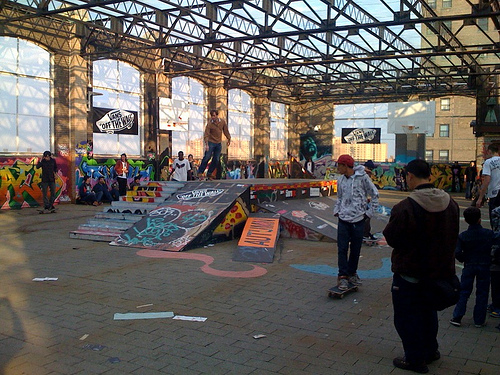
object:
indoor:
[5, 24, 495, 333]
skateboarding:
[180, 109, 326, 183]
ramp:
[109, 182, 252, 252]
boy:
[332, 153, 381, 293]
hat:
[330, 154, 355, 168]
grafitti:
[170, 185, 231, 202]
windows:
[172, 76, 211, 163]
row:
[0, 26, 298, 160]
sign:
[86, 105, 145, 135]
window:
[88, 50, 151, 164]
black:
[290, 199, 304, 210]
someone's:
[33, 150, 68, 212]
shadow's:
[59, 160, 78, 202]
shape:
[130, 247, 268, 279]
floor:
[0, 196, 499, 316]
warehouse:
[0, 0, 499, 373]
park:
[23, 180, 471, 301]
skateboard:
[326, 275, 362, 298]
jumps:
[70, 180, 182, 237]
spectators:
[382, 156, 462, 374]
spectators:
[78, 174, 100, 205]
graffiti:
[1, 159, 298, 206]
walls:
[3, 152, 485, 210]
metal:
[6, 3, 138, 25]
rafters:
[71, 11, 499, 57]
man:
[35, 150, 58, 213]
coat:
[36, 158, 57, 182]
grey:
[332, 284, 342, 293]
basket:
[401, 124, 415, 135]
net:
[403, 127, 414, 138]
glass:
[172, 77, 203, 156]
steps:
[130, 182, 185, 189]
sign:
[238, 217, 282, 248]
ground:
[0, 175, 498, 369]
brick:
[184, 342, 221, 357]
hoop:
[401, 123, 418, 129]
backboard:
[387, 99, 436, 135]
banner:
[158, 96, 189, 131]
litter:
[104, 297, 212, 326]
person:
[196, 111, 232, 181]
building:
[415, 2, 500, 170]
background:
[330, 90, 500, 160]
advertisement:
[89, 108, 137, 135]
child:
[450, 204, 493, 325]